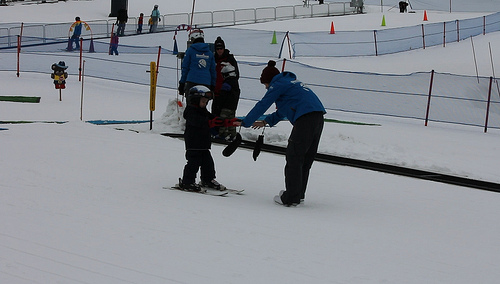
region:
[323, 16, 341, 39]
orange safety cone in snow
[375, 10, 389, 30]
green boundry cone in snow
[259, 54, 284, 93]
black hat with a tassel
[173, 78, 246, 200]
small child on skis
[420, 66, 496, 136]
mesh fence and two poles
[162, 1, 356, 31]
fence sections in a row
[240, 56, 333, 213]
person bending at the waist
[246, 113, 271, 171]
glove dangling from wrist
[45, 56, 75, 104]
sign shaped like a bear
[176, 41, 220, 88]
blue jacket with white logo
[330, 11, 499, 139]
temporary fencing set up on snow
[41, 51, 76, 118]
sign with a cartoon animal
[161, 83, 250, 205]
small child skiing with a helmet on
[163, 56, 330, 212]
adult helping a child on skis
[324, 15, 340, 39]
orange cone far away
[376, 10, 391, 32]
green cone far away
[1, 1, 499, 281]
children's ski slope with adults helping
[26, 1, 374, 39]
three people heading up a ski slope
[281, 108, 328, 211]
black ski pants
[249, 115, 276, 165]
ski glove attached to jacket sleeve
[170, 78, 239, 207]
a boy standing on skiis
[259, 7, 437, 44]
green and red cones on the snow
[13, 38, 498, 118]
a net with red posts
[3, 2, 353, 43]
a metal railing on the snow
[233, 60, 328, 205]
a person with a blue jacket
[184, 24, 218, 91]
a person with a blue hoodie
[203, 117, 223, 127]
a child wearing red and black gloves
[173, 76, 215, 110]
a helmet and googles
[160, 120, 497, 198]
a black track in the snow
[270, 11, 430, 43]
Four cones in the snow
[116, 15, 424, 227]
People on the snow.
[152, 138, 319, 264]
Person on skis.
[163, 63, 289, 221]
Little boy on the skis.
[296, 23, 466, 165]
Fences on the ground.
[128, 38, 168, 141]
Pole in the snow.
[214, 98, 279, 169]
Gloves between the people.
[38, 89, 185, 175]
Snow on the ground.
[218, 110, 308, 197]
Black gloves between the people.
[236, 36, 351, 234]
Person with a blue coat.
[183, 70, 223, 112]
Helmet on the boy.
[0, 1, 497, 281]
the snow on the ground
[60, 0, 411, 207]
the people on the snow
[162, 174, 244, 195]
the skis under the child's feet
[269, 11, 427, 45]
the cones on the snow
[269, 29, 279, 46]
the green cone on the snow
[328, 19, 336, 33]
the orange cone on the snow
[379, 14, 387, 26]
the green cone on the snow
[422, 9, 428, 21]
the orange cone on the snow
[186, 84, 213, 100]
the helmet on the child's head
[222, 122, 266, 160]
the pair of gloves hanging from the person's arms